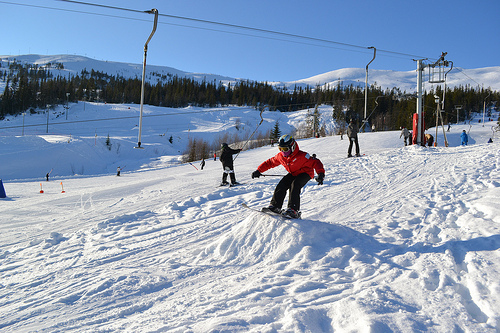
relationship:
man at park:
[252, 134, 326, 219] [2, 122, 494, 328]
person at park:
[219, 142, 243, 187] [2, 122, 494, 328]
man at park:
[347, 118, 360, 157] [2, 122, 494, 328]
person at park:
[395, 121, 413, 151] [2, 122, 494, 328]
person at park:
[457, 122, 473, 145] [2, 122, 494, 328]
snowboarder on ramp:
[241, 134, 326, 219] [194, 205, 365, 263]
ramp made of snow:
[194, 205, 365, 263] [6, 137, 486, 327]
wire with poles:
[0, 0, 445, 67] [128, 7, 163, 148]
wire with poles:
[61, 0, 429, 68] [358, 45, 376, 137]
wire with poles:
[61, 0, 429, 68] [438, 55, 455, 115]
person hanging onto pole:
[217, 141, 239, 187] [230, 102, 275, 161]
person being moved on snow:
[217, 141, 239, 187] [3, 107, 495, 331]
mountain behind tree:
[2, 53, 498, 90] [466, 83, 480, 113]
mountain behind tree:
[2, 53, 498, 90] [394, 96, 408, 123]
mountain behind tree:
[2, 53, 498, 90] [483, 89, 498, 110]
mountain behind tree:
[2, 53, 498, 90] [364, 84, 378, 115]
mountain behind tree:
[2, 53, 498, 90] [306, 88, 320, 108]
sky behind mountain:
[0, 1, 497, 86] [3, 50, 290, 114]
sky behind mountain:
[0, 1, 497, 86] [295, 80, 488, 105]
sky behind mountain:
[0, 1, 497, 86] [310, 59, 441, 87]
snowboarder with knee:
[270, 130, 315, 200] [271, 175, 286, 198]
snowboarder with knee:
[270, 130, 315, 200] [286, 175, 301, 204]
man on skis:
[243, 133, 335, 223] [249, 189, 295, 224]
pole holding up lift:
[407, 56, 424, 152] [421, 57, 453, 87]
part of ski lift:
[132, 9, 160, 152] [1, 0, 497, 145]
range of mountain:
[4, 45, 497, 112] [0, 45, 263, 98]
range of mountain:
[4, 45, 497, 112] [287, 60, 396, 95]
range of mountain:
[4, 45, 497, 112] [321, 65, 491, 92]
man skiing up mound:
[252, 134, 326, 219] [216, 209, 376, 267]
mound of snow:
[216, 209, 376, 267] [8, 166, 492, 328]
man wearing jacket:
[252, 134, 326, 219] [257, 150, 325, 179]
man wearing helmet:
[252, 134, 326, 219] [271, 124, 301, 151]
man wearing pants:
[252, 134, 326, 219] [261, 171, 311, 219]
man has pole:
[252, 134, 326, 219] [258, 172, 285, 180]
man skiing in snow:
[252, 134, 326, 219] [3, 107, 495, 331]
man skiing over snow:
[252, 134, 326, 219] [3, 107, 495, 331]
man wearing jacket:
[252, 134, 326, 219] [209, 126, 247, 180]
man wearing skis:
[252, 134, 326, 219] [247, 181, 309, 219]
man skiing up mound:
[252, 134, 326, 219] [197, 209, 385, 270]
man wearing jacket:
[252, 134, 326, 219] [254, 153, 329, 181]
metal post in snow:
[396, 44, 435, 164] [402, 147, 457, 195]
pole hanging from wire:
[129, 7, 160, 149] [0, 0, 429, 67]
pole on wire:
[351, 69, 392, 125] [197, 6, 342, 61]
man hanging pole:
[344, 109, 361, 159] [351, 69, 392, 125]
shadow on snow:
[300, 214, 500, 271] [3, 107, 495, 331]